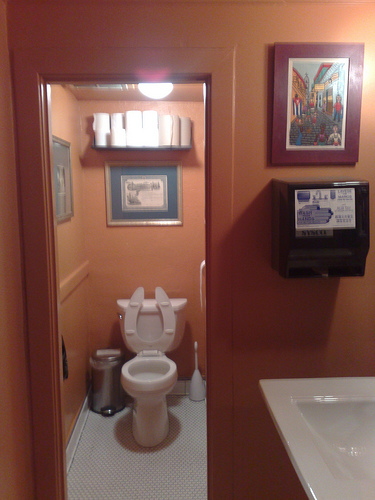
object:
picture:
[271, 46, 363, 169]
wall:
[0, 0, 372, 500]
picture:
[106, 162, 180, 227]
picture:
[44, 137, 75, 220]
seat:
[120, 286, 179, 353]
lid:
[90, 349, 126, 367]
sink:
[286, 367, 373, 500]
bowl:
[120, 351, 177, 385]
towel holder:
[269, 176, 373, 281]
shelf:
[88, 138, 192, 154]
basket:
[89, 346, 127, 417]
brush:
[83, 105, 192, 164]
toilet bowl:
[108, 289, 194, 457]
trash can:
[81, 339, 131, 421]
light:
[137, 84, 173, 100]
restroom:
[47, 79, 207, 499]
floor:
[59, 372, 208, 499]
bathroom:
[38, 80, 216, 468]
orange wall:
[48, 82, 205, 441]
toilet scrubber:
[185, 340, 204, 404]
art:
[269, 40, 365, 168]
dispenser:
[270, 178, 371, 280]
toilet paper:
[93, 113, 111, 147]